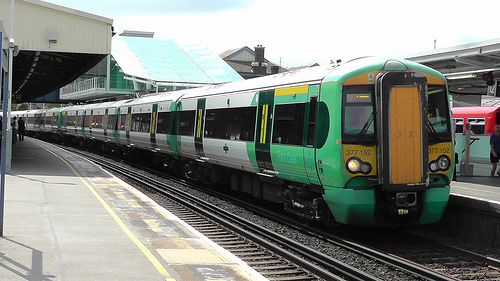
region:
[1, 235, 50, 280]
Shadow of a railing on a platform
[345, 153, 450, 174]
One headlight lit on a train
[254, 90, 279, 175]
Green door on the side of a train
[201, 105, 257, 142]
Passenger window on the side of a train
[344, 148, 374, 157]
377 152 on the front of a train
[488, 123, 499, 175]
Man walking on a train platform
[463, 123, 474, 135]
Woman in front of a red train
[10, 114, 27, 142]
People standing under an awning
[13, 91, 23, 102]
Sign for platform 14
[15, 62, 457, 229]
Green passenger train in a station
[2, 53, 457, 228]
this is green train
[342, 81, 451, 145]
this is a window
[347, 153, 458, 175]
these are some lights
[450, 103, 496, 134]
this is a red train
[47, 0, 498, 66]
this is the blue sky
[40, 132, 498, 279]
these are the train tracks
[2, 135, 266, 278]
that is the platform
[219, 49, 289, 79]
that is a building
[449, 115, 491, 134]
those are the windows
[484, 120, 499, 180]
this is a man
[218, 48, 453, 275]
A green and yellow train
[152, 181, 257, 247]
A metalic train truck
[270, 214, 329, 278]
A metalic train truck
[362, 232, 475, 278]
A metalic train truck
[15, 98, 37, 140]
A person at a waiting bay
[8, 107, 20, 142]
A person at a waiting bay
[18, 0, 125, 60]
A white roof waiting bay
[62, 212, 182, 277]
A grey road besides the truck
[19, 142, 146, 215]
A grey road besides the truck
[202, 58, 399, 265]
Train sitting on the track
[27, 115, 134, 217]
Shadow cast on the pavement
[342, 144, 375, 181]
Headlight on the front of the train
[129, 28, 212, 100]
Roof of the building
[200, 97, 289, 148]
Window on the side of the train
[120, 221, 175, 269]
Yellow paint on the pavement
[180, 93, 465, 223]
Train is made of metal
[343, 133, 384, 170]
The headlight is turned on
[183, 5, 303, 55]
The sky is full of clouds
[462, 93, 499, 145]
Train on other side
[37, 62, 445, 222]
a long green train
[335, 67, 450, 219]
the front view of the train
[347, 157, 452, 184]
the headlights of the train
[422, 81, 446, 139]
the windshield of the train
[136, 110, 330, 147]
some passengers window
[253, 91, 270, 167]
one exit door of the train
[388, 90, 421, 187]
this part is yellow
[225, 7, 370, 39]
the sky in the background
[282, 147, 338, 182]
this part is green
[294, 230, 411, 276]
the metal railroad of the train